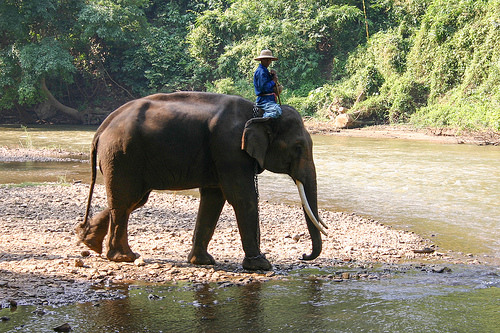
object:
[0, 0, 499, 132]
leaves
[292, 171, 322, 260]
trunk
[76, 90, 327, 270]
elephant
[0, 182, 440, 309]
rock bank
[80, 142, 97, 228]
tail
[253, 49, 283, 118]
man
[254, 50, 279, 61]
hat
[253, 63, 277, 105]
blue shirt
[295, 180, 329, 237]
white tusks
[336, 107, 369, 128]
tree trunk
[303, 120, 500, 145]
ground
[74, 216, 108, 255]
foot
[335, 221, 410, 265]
rocks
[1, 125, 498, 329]
water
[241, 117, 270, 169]
ear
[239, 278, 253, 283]
rocks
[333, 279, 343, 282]
rocks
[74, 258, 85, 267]
rocks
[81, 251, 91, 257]
rocks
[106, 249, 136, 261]
foot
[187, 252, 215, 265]
foot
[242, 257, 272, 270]
foot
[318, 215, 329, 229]
white tusks